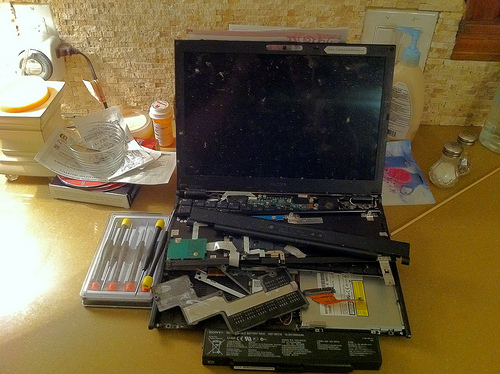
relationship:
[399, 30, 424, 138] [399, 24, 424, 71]
bottle with pump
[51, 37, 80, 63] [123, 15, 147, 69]
plugin on wall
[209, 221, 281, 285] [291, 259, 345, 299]
parts sitting on keyboard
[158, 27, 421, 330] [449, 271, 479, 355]
laptop on surface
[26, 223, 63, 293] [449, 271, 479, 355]
light on surface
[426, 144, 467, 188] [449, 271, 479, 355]
salt shaker on surface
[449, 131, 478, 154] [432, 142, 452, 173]
pepper shaker on shaker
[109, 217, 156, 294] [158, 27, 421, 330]
tools beside laptop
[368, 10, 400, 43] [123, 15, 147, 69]
light switch on wall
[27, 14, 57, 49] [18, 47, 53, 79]
outlet has timer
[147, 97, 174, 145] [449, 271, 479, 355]
medicine bottle on surface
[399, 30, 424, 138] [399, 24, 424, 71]
bottle has pump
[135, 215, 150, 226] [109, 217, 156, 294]
box has tools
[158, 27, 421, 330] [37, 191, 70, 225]
laptop sits on table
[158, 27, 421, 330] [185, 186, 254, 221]
laptop taken apart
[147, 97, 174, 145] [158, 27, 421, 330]
medicine bottle behind laptop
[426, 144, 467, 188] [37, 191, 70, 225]
salt shaker on table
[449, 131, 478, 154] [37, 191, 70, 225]
pepper shaker on table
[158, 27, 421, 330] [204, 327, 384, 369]
laptop has battery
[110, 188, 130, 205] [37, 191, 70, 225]
book on table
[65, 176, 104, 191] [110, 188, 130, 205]
discs are on book